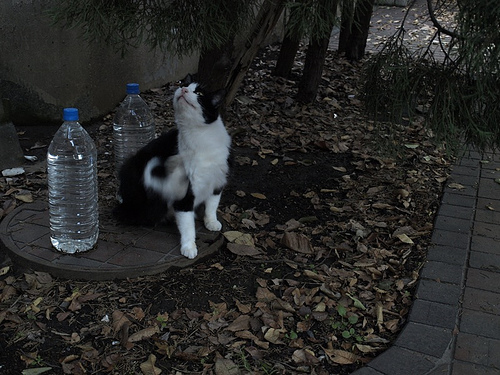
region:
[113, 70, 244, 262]
small black and white domesticated feline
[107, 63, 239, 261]
black and white furry cat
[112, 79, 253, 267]
furry cat with pink nose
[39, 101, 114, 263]
large plastic bottle with blue cap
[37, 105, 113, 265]
tall water bottle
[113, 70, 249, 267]
cat scratching itself with foot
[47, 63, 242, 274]
cat sitting between two water bottles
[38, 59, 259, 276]
cat and water bottles on circular brick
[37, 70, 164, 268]
two tall plastic bottles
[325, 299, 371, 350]
clovers growing through dead leaves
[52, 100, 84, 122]
blue cap of water bottle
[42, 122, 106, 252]
clear plastic water bottle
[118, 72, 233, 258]
black and white cat looking up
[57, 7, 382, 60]
Green trees with brown trunks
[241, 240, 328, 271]
Twigs in the leaves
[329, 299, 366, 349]
green grass growing in the ground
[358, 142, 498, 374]
gray cobblestone walkway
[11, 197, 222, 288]
man hole cover on ground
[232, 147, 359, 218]
Black dirt surrounded by leaves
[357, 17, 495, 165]
green branches hanging down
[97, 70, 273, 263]
The cat is sitting.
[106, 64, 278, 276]
The cat is black and white.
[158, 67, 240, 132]
The cat is looking up.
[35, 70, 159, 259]
Two water bottles are beside the cat.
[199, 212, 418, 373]
The ground is covered with leaves.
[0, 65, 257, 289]
The cat sits on something round.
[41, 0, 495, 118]
Trees are in the background.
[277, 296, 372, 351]
A green plant grows in the ground.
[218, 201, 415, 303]
The leaves are brown.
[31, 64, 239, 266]
The water bottles are as tall as the cat.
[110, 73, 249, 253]
cat is black and white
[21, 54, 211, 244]
water bottles on both sides of cat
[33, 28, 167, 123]
bottles have blue top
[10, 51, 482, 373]
leaves are on ground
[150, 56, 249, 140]
cat is looking upwards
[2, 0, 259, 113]
rock structure behind cat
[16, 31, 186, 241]
water bottles are filled with water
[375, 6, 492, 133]
tree branch is hanging down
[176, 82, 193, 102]
cat's nose is pink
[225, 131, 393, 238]
dirt is on ground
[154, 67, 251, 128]
The cat is looking up.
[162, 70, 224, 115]
The cat is smiling.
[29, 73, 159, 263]
Two water bottles are beside the cat.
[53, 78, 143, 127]
The bottles have blue caps.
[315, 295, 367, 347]
A plant grows in the leaves.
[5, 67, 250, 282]
The cat sits on a round object.